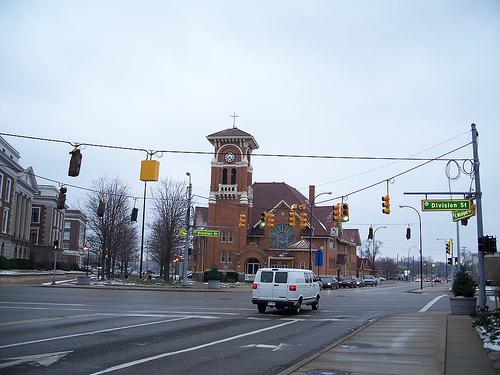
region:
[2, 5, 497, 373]
A suburban street scene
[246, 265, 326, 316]
A van is on the street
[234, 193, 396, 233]
Traffic lights are above the street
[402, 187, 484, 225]
Street name signs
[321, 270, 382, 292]
A line of traffic is stopped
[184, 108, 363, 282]
A church is beside the street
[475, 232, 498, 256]
A crosswalk signal light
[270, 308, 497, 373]
This is a sidewalk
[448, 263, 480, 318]
A small tree is on the corner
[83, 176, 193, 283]
Tress are beside the church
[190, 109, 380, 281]
A big brick church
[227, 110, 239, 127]
a cross on the top of the church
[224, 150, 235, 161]
A clock on the church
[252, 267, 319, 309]
a white van driving down the street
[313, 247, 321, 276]
A blue sign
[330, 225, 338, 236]
a white left turn sign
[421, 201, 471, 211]
division st sign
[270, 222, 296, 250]
a stain glass church window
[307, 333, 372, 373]
two manhole covers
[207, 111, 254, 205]
a church steeple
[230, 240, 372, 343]
the van is white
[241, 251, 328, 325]
the van is white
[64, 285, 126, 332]
the pavement is wet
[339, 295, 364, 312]
the pavement is wet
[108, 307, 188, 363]
the pavement is wet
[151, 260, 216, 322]
the pavement is wet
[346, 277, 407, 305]
the pavement is wet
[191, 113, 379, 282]
A church on a busy street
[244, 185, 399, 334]
A white van going on green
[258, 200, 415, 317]
Traffic on a city street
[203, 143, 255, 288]
A clock tower on a church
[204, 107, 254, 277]
The steeple and clock tower of a church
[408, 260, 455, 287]
Red light for traffic in the distance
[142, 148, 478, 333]
A busy intersection in front of church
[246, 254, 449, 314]
City traffic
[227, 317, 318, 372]
Right turn only lane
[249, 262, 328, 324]
A white van in the intersection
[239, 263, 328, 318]
A white van on the road.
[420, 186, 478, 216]
a street sign on a ploe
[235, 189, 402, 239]
a group of stop lights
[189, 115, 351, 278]
a chruch in the middle of street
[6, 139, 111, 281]
buildings along the street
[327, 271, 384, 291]
a line of cars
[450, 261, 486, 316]
a tree in a pot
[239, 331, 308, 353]
a white arrow on the road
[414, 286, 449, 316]
a white line on the road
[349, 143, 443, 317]
a cable across the road